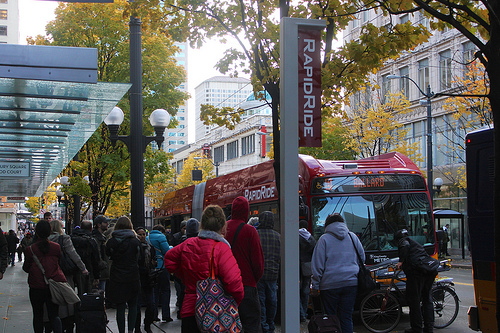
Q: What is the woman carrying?
A: A purse.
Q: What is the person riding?
A: A bicycle.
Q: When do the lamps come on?
A: At night.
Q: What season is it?
A: Fall.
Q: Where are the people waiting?
A: The sidewalk.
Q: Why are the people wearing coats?
A: It's chilly.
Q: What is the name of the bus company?
A: RapidRide.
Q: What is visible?
A: The crowd.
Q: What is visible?
A: The crowd.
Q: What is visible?
A: The crowd.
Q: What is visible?
A: The crowd.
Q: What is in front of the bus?
A: The man with a bicycle.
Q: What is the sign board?
A: Red.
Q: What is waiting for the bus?
A: The group of people.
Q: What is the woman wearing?
A: Red jacket.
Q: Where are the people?
A: On the sidewalk.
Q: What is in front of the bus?
A: Bike.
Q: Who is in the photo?
A: Some people.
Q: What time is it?
A: Afternoon.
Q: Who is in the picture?
A: Men and women.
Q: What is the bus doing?
A: Picking people.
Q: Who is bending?
A: The cyclist.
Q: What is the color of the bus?
A: Red.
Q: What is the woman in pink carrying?
A: A bag.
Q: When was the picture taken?
A: During the day.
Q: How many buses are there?
A: 1.